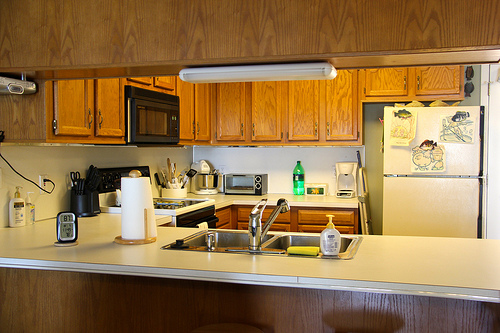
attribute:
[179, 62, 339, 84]
light — white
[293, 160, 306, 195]
soda bottle — green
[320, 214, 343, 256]
soap container — white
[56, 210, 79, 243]
clock — black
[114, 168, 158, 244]
paper towel holder — wooden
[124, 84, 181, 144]
microwave — black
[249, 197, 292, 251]
faucet — silver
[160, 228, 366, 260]
sink — stainless steel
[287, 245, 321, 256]
sponge — yellow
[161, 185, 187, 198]
container — round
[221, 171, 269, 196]
toaster oven — black, silver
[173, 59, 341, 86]
light — white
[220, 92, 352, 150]
cabinets — brown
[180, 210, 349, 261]
sink — double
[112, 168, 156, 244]
holder — wooden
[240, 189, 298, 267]
faucet — stainless steel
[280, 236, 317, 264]
sponge — yellow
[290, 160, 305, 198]
soda bottle — lime green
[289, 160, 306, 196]
bottle — green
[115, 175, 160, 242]
paper towel — white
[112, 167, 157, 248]
towel holder — wooden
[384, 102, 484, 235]
refrigerator — white